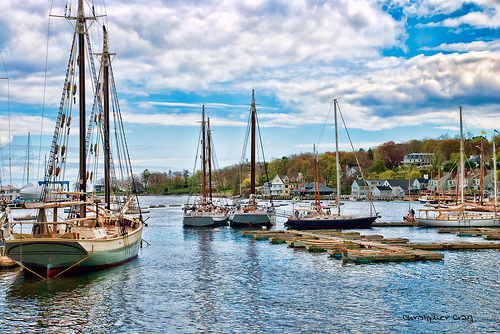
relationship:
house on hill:
[399, 148, 439, 170] [374, 140, 492, 181]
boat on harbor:
[11, 202, 152, 275] [203, 250, 358, 327]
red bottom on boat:
[19, 255, 146, 282] [8, 5, 146, 288]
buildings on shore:
[341, 175, 415, 207] [342, 196, 422, 223]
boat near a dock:
[284, 207, 382, 228] [279, 226, 435, 269]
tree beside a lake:
[184, 168, 191, 183] [161, 225, 201, 288]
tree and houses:
[249, 153, 429, 201] [286, 173, 408, 210]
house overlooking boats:
[399, 148, 439, 170] [302, 95, 499, 245]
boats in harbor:
[302, 95, 499, 245] [4, 192, 474, 331]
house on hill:
[399, 148, 439, 170] [317, 132, 497, 204]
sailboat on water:
[35, 40, 125, 316] [13, 200, 185, 309]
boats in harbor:
[157, 76, 395, 241] [186, 164, 449, 220]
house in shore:
[262, 175, 289, 195] [181, 174, 495, 197]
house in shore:
[349, 172, 381, 194] [181, 174, 495, 197]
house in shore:
[412, 178, 428, 189] [181, 174, 495, 197]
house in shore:
[427, 170, 447, 191] [181, 174, 495, 197]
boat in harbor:
[401, 204, 493, 227] [179, 171, 486, 211]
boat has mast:
[180, 99, 227, 231] [193, 94, 216, 210]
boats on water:
[184, 194, 299, 240] [212, 233, 359, 312]